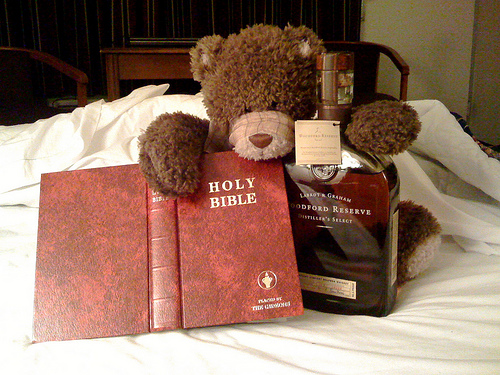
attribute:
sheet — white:
[12, 79, 477, 364]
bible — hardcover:
[37, 153, 293, 328]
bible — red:
[45, 167, 367, 315]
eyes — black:
[232, 96, 282, 114]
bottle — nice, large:
[282, 51, 400, 316]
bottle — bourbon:
[273, 30, 413, 320]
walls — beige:
[352, 0, 493, 120]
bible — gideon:
[26, 142, 306, 341]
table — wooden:
[93, 33, 201, 100]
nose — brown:
[249, 132, 273, 149]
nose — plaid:
[228, 112, 294, 159]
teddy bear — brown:
[135, 20, 445, 297]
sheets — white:
[2, 80, 499, 371]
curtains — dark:
[323, 8, 359, 86]